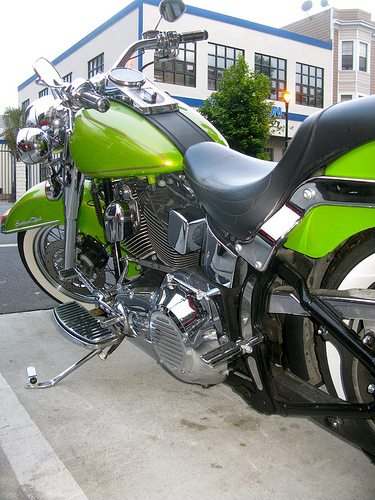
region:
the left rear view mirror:
[20, 47, 89, 100]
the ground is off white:
[25, 375, 221, 483]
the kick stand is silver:
[2, 345, 111, 393]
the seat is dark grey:
[165, 106, 343, 244]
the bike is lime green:
[0, 26, 354, 265]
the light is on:
[257, 70, 301, 120]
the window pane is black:
[288, 53, 333, 103]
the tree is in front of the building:
[166, 34, 287, 145]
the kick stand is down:
[10, 336, 113, 404]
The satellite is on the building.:
[299, 0, 316, 19]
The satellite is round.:
[300, 1, 313, 17]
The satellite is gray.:
[297, 0, 318, 18]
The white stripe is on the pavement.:
[0, 431, 95, 499]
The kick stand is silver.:
[20, 356, 101, 387]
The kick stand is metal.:
[23, 356, 94, 389]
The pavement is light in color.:
[83, 416, 196, 481]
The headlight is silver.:
[14, 123, 51, 167]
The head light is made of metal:
[14, 128, 51, 163]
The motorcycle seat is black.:
[194, 133, 332, 191]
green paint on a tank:
[88, 124, 114, 156]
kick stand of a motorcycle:
[24, 353, 115, 391]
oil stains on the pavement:
[155, 406, 227, 444]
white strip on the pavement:
[33, 414, 64, 475]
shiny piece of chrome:
[166, 293, 190, 323]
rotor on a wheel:
[37, 242, 99, 292]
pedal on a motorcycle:
[49, 299, 116, 354]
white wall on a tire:
[19, 235, 37, 274]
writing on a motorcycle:
[11, 213, 46, 228]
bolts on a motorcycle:
[229, 236, 270, 274]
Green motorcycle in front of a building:
[0, 48, 373, 414]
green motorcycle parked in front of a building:
[15, 7, 373, 423]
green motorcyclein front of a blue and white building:
[27, 13, 373, 425]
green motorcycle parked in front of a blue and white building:
[17, 4, 373, 403]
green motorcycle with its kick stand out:
[19, 54, 364, 395]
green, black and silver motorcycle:
[11, 27, 371, 414]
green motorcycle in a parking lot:
[18, 52, 370, 406]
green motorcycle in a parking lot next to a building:
[23, 20, 373, 413]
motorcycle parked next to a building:
[18, 11, 359, 414]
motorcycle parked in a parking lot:
[15, 52, 368, 406]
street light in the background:
[275, 82, 295, 106]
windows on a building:
[204, 48, 236, 92]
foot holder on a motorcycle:
[200, 326, 254, 374]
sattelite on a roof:
[295, 0, 331, 22]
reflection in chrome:
[172, 297, 197, 341]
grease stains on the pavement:
[179, 401, 228, 447]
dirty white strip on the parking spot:
[21, 449, 53, 478]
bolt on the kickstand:
[22, 373, 45, 389]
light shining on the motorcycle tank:
[108, 120, 178, 180]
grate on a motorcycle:
[154, 319, 179, 360]